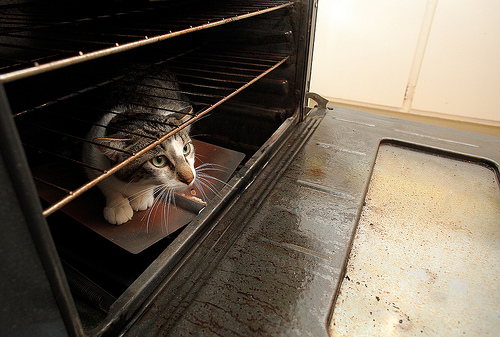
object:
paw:
[105, 195, 134, 226]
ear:
[90, 133, 131, 163]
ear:
[166, 105, 194, 124]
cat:
[81, 72, 234, 225]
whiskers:
[105, 163, 234, 235]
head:
[94, 105, 197, 192]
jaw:
[149, 170, 180, 193]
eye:
[149, 154, 170, 171]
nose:
[177, 164, 194, 190]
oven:
[4, 0, 327, 331]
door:
[128, 76, 498, 335]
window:
[0, 0, 319, 337]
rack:
[0, 0, 296, 218]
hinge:
[307, 91, 330, 110]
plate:
[33, 105, 247, 255]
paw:
[129, 184, 159, 212]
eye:
[183, 139, 193, 157]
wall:
[308, 0, 499, 128]